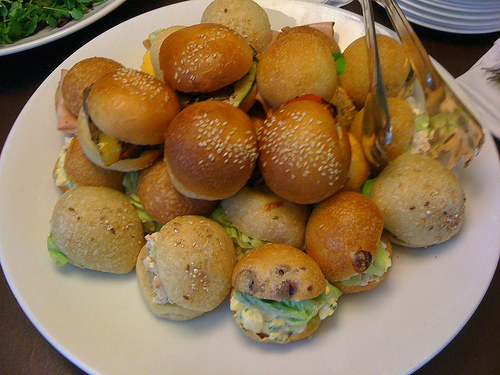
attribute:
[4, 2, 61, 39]
lettuce — green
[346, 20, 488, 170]
tongs — silver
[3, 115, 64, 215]
plate — white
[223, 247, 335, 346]
sandwich — light brown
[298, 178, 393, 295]
sandwich — light brown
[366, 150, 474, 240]
sandwich — light brown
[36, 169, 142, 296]
sandwich — light brown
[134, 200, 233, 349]
sandwich — light brown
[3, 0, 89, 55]
green lettuce — dark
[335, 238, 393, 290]
lettuce — green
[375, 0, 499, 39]
plates — stack, Blue 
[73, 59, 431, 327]
sandwiches — ready to eat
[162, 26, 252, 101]
bun — Tan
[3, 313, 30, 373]
table — brown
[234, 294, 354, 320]
lettuce — green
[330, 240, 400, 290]
lettuce — green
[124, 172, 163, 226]
lettuce — green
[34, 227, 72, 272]
lettuce — green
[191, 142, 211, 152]
seeds — sesame seeds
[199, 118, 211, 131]
seeds — sesame seeds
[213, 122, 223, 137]
seeds — sesame seeds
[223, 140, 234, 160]
seeds — sesame seeds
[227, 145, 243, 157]
seeds — sesame seeds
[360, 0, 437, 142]
tongs — metal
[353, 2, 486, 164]
tongs — Silver 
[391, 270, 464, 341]
plates — white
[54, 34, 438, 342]
sandwiches — mini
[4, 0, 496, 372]
plate — circular, white, round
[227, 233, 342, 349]
sandwich — small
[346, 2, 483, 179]
tongs — Shiny, Silver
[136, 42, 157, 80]
cheese — orange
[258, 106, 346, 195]
seeds — white, sesame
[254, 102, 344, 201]
specks — white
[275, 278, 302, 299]
dot — black